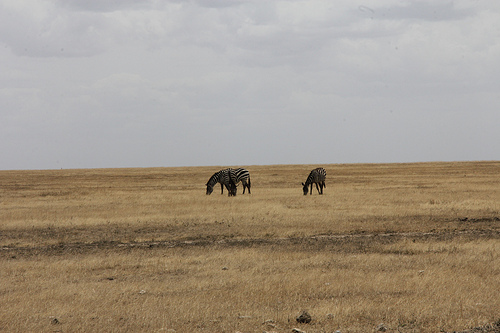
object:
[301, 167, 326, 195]
zebra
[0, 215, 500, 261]
dirt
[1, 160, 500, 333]
grass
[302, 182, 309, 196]
head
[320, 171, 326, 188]
tail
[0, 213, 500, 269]
path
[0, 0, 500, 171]
cloud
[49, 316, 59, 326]
rocks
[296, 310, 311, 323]
rock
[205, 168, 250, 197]
zebra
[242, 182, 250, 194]
leg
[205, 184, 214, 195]
head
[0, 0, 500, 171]
sky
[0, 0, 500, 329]
barron landscape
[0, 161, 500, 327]
field